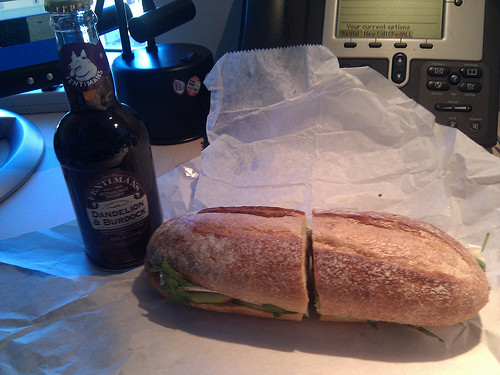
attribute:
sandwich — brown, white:
[140, 210, 496, 322]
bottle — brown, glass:
[43, 2, 166, 265]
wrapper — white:
[0, 53, 499, 373]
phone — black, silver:
[241, 4, 499, 149]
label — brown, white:
[73, 166, 154, 238]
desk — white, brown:
[7, 95, 493, 249]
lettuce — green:
[151, 264, 204, 294]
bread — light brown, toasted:
[312, 209, 488, 324]